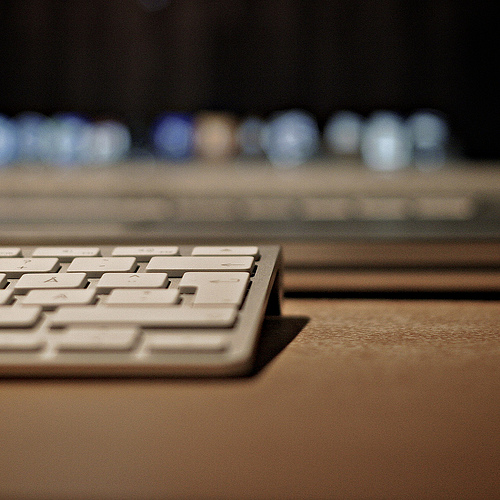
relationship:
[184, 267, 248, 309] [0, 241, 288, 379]
key on key board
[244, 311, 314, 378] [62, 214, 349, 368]
shadow of keyboard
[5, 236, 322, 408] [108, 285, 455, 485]
key board on brown surface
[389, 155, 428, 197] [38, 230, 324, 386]
wall on board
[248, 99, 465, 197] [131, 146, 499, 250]
blurry objects on mantel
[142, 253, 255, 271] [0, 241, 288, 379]
key on key board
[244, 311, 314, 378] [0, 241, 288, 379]
shadow below key board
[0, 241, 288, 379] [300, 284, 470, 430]
key board on surface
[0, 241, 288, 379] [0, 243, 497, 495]
key board on table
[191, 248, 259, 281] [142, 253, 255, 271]
arrow on key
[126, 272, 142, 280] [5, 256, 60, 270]
symbol on a key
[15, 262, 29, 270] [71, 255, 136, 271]
symbol on a key